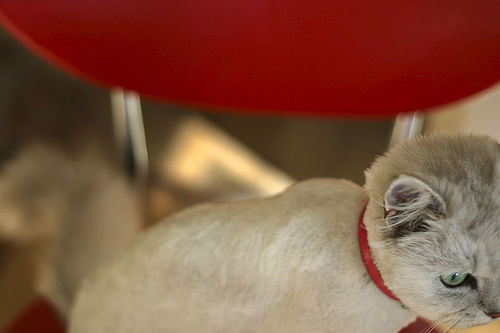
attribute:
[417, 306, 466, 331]
whiskers — tall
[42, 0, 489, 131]
table — red, semi circular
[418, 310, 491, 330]
whiskers — white, black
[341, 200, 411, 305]
red collar — bright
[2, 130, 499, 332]
fur — grey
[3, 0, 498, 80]
chair back — red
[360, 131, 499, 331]
head — black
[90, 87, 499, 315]
kitten — grey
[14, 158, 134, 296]
tail — long, white, gray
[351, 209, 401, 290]
collar — red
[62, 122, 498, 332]
fur — grey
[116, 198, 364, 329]
fur — grey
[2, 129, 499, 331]
cat — gray, white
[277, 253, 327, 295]
fur — grey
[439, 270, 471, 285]
eye — blue, yellow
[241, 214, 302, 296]
fur — grey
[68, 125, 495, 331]
cat — curious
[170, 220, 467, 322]
highlights — grey , black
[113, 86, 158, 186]
support — chrome, metal, colored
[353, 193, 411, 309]
collar — red